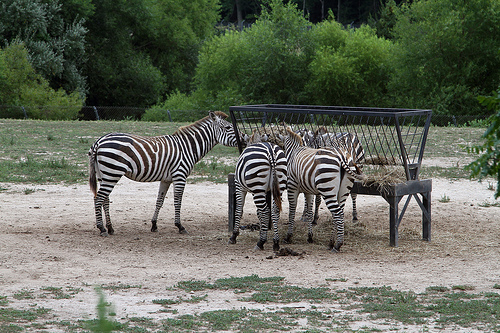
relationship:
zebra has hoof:
[78, 110, 253, 240] [98, 228, 111, 239]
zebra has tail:
[78, 110, 253, 240] [84, 143, 101, 200]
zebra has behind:
[78, 110, 253, 240] [89, 130, 120, 183]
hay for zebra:
[247, 125, 297, 144] [78, 110, 253, 240]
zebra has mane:
[78, 110, 253, 240] [170, 104, 230, 135]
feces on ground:
[266, 244, 305, 264] [4, 121, 500, 333]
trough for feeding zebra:
[227, 99, 439, 258] [78, 110, 253, 240]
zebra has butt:
[227, 128, 292, 255] [243, 145, 291, 196]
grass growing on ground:
[168, 276, 215, 295] [4, 121, 500, 333]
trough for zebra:
[227, 99, 439, 258] [78, 110, 253, 240]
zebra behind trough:
[78, 110, 253, 240] [227, 99, 439, 258]